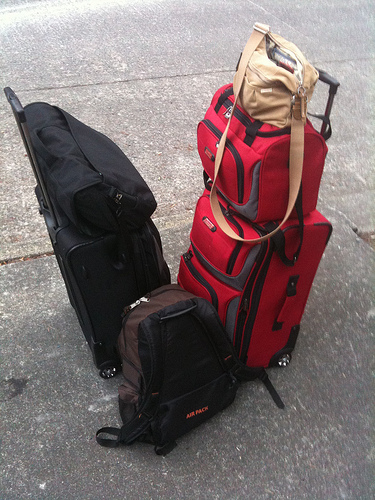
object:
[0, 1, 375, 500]
ground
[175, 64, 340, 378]
bag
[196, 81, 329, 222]
bag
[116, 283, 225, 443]
bag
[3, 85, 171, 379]
luggage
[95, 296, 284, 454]
backpack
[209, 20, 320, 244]
bag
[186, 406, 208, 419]
logo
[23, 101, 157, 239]
bag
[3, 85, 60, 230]
handle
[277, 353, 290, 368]
wheel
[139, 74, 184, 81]
crack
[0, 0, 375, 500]
sidewalk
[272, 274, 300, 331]
handle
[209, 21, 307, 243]
strap